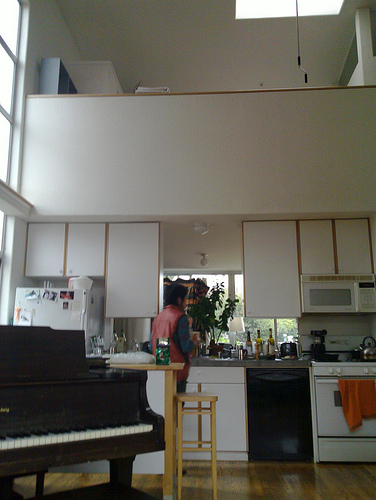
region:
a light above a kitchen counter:
[185, 221, 214, 242]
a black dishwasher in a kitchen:
[240, 361, 318, 467]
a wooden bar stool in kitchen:
[170, 384, 228, 498]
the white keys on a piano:
[79, 422, 136, 438]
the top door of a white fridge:
[13, 284, 95, 326]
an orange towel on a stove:
[331, 375, 374, 434]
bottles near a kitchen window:
[244, 324, 283, 358]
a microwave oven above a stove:
[296, 270, 375, 318]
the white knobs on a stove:
[319, 363, 346, 379]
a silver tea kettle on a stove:
[347, 335, 374, 359]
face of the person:
[144, 270, 212, 324]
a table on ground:
[166, 410, 239, 495]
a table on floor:
[173, 396, 240, 498]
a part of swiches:
[12, 418, 128, 453]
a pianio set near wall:
[6, 338, 147, 480]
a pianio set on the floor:
[9, 317, 202, 491]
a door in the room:
[241, 356, 325, 496]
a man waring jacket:
[123, 277, 205, 370]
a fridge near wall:
[6, 275, 110, 329]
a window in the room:
[172, 252, 326, 362]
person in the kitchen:
[147, 263, 215, 381]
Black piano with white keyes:
[1, 324, 163, 498]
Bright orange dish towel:
[337, 377, 375, 431]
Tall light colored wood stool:
[173, 391, 218, 498]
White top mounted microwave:
[299, 273, 375, 317]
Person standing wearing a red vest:
[150, 284, 193, 392]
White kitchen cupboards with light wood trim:
[240, 218, 373, 317]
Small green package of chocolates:
[155, 336, 171, 365]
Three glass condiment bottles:
[244, 327, 277, 357]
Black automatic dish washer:
[244, 364, 313, 462]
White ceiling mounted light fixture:
[192, 221, 211, 236]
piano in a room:
[0, 320, 172, 498]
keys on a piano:
[0, 416, 158, 456]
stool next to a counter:
[172, 388, 221, 498]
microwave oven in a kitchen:
[295, 268, 375, 317]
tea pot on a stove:
[357, 332, 375, 362]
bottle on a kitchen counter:
[265, 324, 278, 359]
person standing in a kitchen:
[148, 280, 190, 478]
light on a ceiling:
[195, 248, 215, 268]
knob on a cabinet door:
[149, 306, 159, 317]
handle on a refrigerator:
[78, 286, 89, 333]